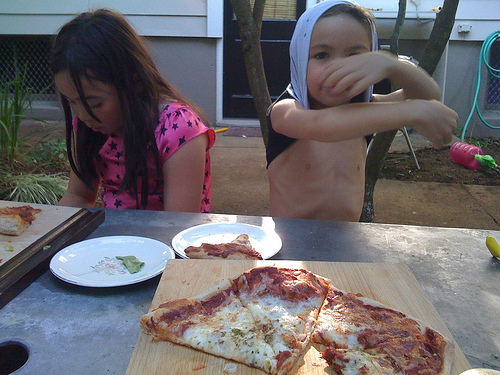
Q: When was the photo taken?
A: Daytime.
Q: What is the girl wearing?
A: Her shirt.